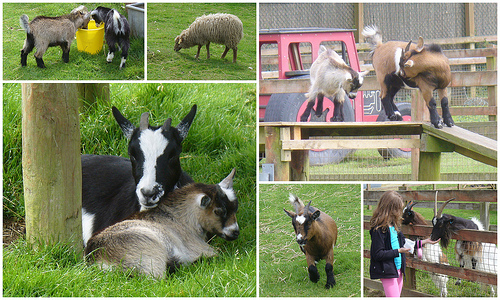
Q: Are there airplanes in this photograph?
A: No, there are no airplanes.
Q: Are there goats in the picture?
A: Yes, there is a goat.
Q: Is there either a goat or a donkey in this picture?
A: Yes, there is a goat.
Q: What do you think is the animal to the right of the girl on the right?
A: The animal is a goat.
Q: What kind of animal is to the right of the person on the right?
A: The animal is a goat.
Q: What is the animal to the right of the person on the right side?
A: The animal is a goat.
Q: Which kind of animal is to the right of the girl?
A: The animal is a goat.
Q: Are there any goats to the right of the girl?
A: Yes, there is a goat to the right of the girl.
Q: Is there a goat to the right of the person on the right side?
A: Yes, there is a goat to the right of the girl.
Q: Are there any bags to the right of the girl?
A: No, there is a goat to the right of the girl.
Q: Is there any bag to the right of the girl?
A: No, there is a goat to the right of the girl.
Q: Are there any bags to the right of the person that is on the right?
A: No, there is a goat to the right of the girl.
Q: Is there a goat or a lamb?
A: Yes, there is a goat.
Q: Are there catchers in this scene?
A: No, there are no catchers.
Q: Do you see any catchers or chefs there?
A: No, there are no catchers or chefs.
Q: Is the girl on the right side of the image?
A: Yes, the girl is on the right of the image.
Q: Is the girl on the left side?
A: No, the girl is on the right of the image.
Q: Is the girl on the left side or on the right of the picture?
A: The girl is on the right of the image.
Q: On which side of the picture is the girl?
A: The girl is on the right of the image.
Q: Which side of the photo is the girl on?
A: The girl is on the right of the image.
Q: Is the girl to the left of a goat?
A: Yes, the girl is to the left of a goat.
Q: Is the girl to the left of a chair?
A: No, the girl is to the left of a goat.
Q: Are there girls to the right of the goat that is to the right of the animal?
A: Yes, there is a girl to the right of the goat.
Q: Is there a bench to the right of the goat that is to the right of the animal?
A: No, there is a girl to the right of the goat.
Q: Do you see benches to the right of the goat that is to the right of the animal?
A: No, there is a girl to the right of the goat.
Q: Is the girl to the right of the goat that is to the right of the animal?
A: Yes, the girl is to the right of the goat.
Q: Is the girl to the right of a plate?
A: No, the girl is to the right of the goat.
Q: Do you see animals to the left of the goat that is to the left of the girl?
A: Yes, there is an animal to the left of the goat.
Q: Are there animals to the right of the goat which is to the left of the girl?
A: No, the animal is to the left of the goat.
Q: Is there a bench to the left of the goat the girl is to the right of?
A: No, there is an animal to the left of the goat.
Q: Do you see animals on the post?
A: Yes, there is an animal on the post.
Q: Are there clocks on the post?
A: No, there is an animal on the post.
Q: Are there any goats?
A: Yes, there is a goat.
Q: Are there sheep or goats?
A: Yes, there is a goat.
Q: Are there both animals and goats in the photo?
A: Yes, there are both a goat and animals.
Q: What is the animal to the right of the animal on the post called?
A: The animal is a goat.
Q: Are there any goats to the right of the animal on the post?
A: Yes, there is a goat to the right of the animal.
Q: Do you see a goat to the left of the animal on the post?
A: No, the goat is to the right of the animal.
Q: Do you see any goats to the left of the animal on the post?
A: No, the goat is to the right of the animal.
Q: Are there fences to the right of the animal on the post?
A: No, there is a goat to the right of the animal.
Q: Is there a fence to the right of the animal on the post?
A: No, there is a goat to the right of the animal.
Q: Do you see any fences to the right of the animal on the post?
A: No, there is a goat to the right of the animal.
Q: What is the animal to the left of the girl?
A: The animal is a goat.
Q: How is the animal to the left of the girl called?
A: The animal is a goat.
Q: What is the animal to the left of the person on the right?
A: The animal is a goat.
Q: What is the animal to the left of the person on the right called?
A: The animal is a goat.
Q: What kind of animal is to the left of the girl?
A: The animal is a goat.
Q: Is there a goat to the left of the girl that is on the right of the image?
A: Yes, there is a goat to the left of the girl.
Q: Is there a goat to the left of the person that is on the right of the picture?
A: Yes, there is a goat to the left of the girl.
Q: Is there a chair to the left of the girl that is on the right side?
A: No, there is a goat to the left of the girl.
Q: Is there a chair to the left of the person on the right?
A: No, there is a goat to the left of the girl.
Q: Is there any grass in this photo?
A: Yes, there is grass.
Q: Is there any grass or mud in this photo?
A: Yes, there is grass.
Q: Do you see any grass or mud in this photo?
A: Yes, there is grass.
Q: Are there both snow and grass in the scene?
A: No, there is grass but no snow.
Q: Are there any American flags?
A: No, there are no American flags.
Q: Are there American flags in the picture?
A: No, there are no American flags.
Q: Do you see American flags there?
A: No, there are no American flags.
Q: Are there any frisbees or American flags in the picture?
A: No, there are no American flags or frisbees.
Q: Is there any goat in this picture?
A: Yes, there is a goat.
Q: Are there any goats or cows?
A: Yes, there is a goat.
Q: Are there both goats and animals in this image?
A: Yes, there are both a goat and an animal.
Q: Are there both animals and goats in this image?
A: Yes, there are both a goat and an animal.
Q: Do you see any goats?
A: Yes, there are goats.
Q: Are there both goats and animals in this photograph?
A: Yes, there are both goats and an animal.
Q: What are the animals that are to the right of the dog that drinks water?
A: The animals are goats.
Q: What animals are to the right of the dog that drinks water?
A: The animals are goats.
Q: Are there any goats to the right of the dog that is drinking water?
A: Yes, there are goats to the right of the dog.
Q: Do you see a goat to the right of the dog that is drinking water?
A: Yes, there are goats to the right of the dog.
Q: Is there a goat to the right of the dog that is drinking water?
A: Yes, there are goats to the right of the dog.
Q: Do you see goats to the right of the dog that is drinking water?
A: Yes, there are goats to the right of the dog.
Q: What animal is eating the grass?
A: The goats are eating the grass.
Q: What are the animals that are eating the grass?
A: The animals are goats.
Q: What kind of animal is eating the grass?
A: The animals are goats.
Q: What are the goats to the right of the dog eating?
A: The goats are eating grass.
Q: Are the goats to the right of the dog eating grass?
A: Yes, the goats are eating grass.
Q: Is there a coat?
A: Yes, there is a coat.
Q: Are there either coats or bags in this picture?
A: Yes, there is a coat.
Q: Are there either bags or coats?
A: Yes, there is a coat.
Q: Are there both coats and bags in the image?
A: No, there is a coat but no bags.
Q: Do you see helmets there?
A: No, there are no helmets.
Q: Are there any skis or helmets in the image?
A: No, there are no helmets or skis.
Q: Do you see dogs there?
A: Yes, there is a dog.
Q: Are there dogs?
A: Yes, there is a dog.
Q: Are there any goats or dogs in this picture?
A: Yes, there is a dog.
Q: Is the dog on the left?
A: Yes, the dog is on the left of the image.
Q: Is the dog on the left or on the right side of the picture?
A: The dog is on the left of the image.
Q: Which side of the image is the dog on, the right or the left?
A: The dog is on the left of the image.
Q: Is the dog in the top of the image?
A: Yes, the dog is in the top of the image.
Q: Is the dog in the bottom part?
A: No, the dog is in the top of the image.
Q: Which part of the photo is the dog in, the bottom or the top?
A: The dog is in the top of the image.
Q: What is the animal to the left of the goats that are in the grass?
A: The animal is a dog.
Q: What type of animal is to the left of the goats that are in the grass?
A: The animal is a dog.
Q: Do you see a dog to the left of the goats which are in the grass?
A: Yes, there is a dog to the left of the goats.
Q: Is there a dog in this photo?
A: Yes, there is a dog.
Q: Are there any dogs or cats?
A: Yes, there is a dog.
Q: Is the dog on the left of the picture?
A: Yes, the dog is on the left of the image.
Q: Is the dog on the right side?
A: No, the dog is on the left of the image.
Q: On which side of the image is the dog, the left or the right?
A: The dog is on the left of the image.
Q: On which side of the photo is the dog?
A: The dog is on the left of the image.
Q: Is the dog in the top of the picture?
A: Yes, the dog is in the top of the image.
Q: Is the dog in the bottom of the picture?
A: No, the dog is in the top of the image.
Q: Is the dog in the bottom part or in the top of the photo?
A: The dog is in the top of the image.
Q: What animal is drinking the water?
A: The dog is drinking the water.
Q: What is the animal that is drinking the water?
A: The animal is a dog.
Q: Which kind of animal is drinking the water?
A: The animal is a dog.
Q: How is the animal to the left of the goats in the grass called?
A: The animal is a dog.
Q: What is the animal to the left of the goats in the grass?
A: The animal is a dog.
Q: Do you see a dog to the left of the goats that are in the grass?
A: Yes, there is a dog to the left of the goats.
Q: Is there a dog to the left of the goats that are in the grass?
A: Yes, there is a dog to the left of the goats.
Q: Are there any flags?
A: No, there are no flags.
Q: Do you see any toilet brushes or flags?
A: No, there are no flags or toilet brushes.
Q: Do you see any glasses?
A: No, there are no glasses.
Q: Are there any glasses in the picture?
A: No, there are no glasses.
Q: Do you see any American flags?
A: No, there are no American flags.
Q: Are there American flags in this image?
A: No, there are no American flags.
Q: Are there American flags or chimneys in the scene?
A: No, there are no American flags or chimneys.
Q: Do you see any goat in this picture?
A: Yes, there is a goat.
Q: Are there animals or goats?
A: Yes, there is a goat.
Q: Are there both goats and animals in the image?
A: Yes, there are both a goat and an animal.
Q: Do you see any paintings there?
A: No, there are no paintings.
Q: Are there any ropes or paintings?
A: No, there are no paintings or ropes.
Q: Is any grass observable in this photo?
A: Yes, there is grass.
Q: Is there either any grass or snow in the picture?
A: Yes, there is grass.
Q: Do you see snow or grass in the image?
A: Yes, there is grass.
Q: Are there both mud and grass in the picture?
A: No, there is grass but no mud.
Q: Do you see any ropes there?
A: No, there are no ropes.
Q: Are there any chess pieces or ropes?
A: No, there are no ropes or chess pieces.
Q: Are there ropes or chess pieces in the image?
A: No, there are no ropes or chess pieces.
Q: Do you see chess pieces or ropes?
A: No, there are no ropes or chess pieces.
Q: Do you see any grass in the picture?
A: Yes, there is grass.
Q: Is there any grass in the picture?
A: Yes, there is grass.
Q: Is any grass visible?
A: Yes, there is grass.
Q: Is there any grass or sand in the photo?
A: Yes, there is grass.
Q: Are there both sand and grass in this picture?
A: No, there is grass but no sand.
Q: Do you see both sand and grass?
A: No, there is grass but no sand.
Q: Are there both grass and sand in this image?
A: No, there is grass but no sand.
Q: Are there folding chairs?
A: No, there are no folding chairs.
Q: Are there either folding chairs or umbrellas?
A: No, there are no folding chairs or umbrellas.